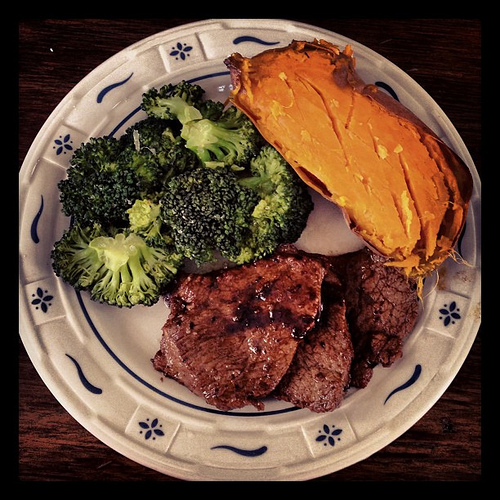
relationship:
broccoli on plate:
[44, 78, 319, 313] [13, 14, 484, 483]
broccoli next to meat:
[44, 78, 319, 313] [144, 241, 422, 422]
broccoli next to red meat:
[44, 78, 319, 313] [144, 241, 422, 422]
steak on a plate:
[144, 241, 422, 422] [13, 14, 484, 483]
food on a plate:
[45, 36, 477, 430] [13, 14, 484, 483]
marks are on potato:
[294, 67, 427, 233] [220, 30, 478, 286]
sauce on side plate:
[323, 235, 378, 301] [13, 14, 484, 483]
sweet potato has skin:
[220, 30, 478, 286] [266, 141, 338, 213]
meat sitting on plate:
[144, 241, 422, 422] [13, 14, 484, 483]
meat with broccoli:
[144, 241, 422, 422] [44, 78, 319, 313]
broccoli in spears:
[44, 78, 319, 313] [136, 77, 270, 178]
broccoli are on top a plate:
[44, 78, 319, 313] [13, 14, 484, 483]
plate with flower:
[13, 14, 490, 493] [164, 34, 197, 63]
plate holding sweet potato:
[13, 14, 484, 483] [220, 30, 478, 286]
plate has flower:
[13, 14, 490, 493] [164, 34, 199, 64]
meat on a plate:
[144, 241, 422, 422] [13, 14, 484, 483]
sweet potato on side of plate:
[220, 30, 478, 286] [13, 14, 490, 493]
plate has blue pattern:
[13, 14, 490, 493] [30, 286, 109, 419]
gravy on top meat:
[200, 275, 319, 345] [144, 241, 422, 422]